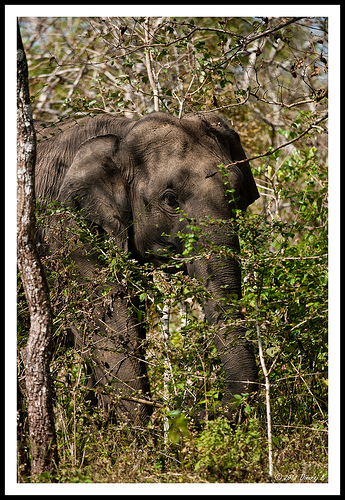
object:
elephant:
[26, 110, 261, 457]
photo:
[14, 18, 328, 482]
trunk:
[200, 267, 262, 418]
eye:
[156, 191, 181, 205]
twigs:
[222, 45, 280, 83]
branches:
[50, 40, 100, 83]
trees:
[215, 40, 312, 121]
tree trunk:
[18, 269, 67, 483]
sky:
[307, 30, 325, 37]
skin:
[72, 122, 128, 138]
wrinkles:
[47, 155, 65, 171]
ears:
[57, 133, 130, 258]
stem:
[21, 313, 51, 402]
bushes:
[176, 417, 270, 464]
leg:
[72, 291, 155, 432]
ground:
[163, 436, 275, 485]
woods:
[188, 43, 255, 85]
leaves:
[187, 54, 229, 82]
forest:
[41, 69, 136, 112]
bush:
[67, 414, 135, 461]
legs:
[51, 292, 177, 452]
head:
[51, 113, 259, 272]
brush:
[276, 312, 323, 462]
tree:
[11, 80, 38, 188]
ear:
[181, 112, 261, 209]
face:
[135, 157, 247, 269]